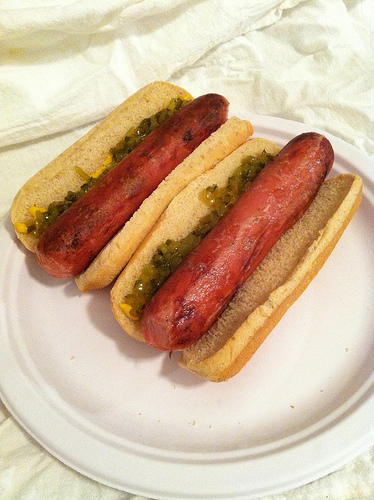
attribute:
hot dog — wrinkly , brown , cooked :
[28, 85, 232, 285]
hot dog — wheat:
[129, 129, 333, 353]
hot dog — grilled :
[25, 93, 212, 277]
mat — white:
[24, 382, 121, 466]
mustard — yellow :
[13, 220, 33, 240]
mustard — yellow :
[80, 146, 123, 182]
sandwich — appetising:
[108, 134, 363, 382]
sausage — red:
[96, 180, 128, 204]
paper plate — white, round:
[2, 111, 369, 497]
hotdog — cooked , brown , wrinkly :
[8, 79, 241, 294]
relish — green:
[22, 74, 287, 313]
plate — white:
[2, 113, 373, 494]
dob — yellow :
[14, 220, 28, 235]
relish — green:
[124, 151, 275, 308]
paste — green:
[198, 188, 228, 202]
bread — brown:
[189, 166, 367, 390]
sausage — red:
[114, 107, 364, 352]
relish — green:
[129, 147, 284, 300]